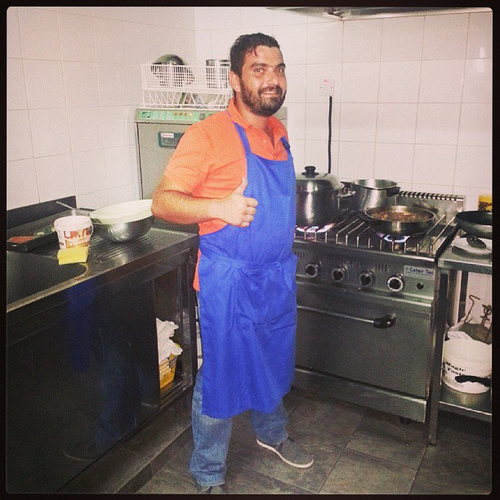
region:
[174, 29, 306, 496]
a man in a blue apron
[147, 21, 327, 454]
a man in an orange shirt and a blue apron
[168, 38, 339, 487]
a man wearing an orange shirt and a blue apron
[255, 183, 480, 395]
a stove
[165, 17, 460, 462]
a man cooking on the stove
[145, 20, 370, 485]
a man giving the thumbs up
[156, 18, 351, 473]
a man posing for a picture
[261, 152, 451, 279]
food cooking on the stove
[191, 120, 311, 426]
long blue apron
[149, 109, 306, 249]
orange shirt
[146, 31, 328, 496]
Man cooking in kitchen.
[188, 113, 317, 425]
Man wearing a blue apron.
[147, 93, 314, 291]
Man dressed in orange shirt.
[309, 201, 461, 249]
Frying pan filled with cooking food.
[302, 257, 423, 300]
Control knobs on front of stove.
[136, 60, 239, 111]
White rack filled with aluminum bowls.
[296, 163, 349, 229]
Covered pot on top of stove.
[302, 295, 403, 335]
Handle on front of oven door.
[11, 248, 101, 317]
Edge of kitchen sink.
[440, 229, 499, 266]
Spoon laying on small plate on counter.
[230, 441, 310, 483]
grey and black mens sneakers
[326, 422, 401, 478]
gray and dark gray stone floor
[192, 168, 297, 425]
bright blue mens apron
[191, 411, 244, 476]
light blue mens jeans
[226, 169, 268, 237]
hand showing the thumbs up sign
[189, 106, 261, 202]
orange colored polo t shirt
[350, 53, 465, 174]
white kitchen tile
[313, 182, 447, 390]
large stainless steel kitchen stove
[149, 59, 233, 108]
white dish rack above washer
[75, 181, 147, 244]
mixing and serving bowl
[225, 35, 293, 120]
a man's face sporting a beard.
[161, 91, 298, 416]
a blue apron tied in front.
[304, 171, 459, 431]
a large stainless steel range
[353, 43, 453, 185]
a white tile backsplash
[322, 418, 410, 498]
a grey ceramic tile floor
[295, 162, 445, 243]
pots and pans of food on the range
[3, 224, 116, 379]
a large stainless steel sink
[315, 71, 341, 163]
an electrical outlet with a flashing red timer.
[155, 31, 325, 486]
A man wearing an orange shirt, blue apron and blue jeans.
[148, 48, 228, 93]
cooking utensils in a wire basket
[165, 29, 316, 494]
man with a blue apron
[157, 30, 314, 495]
man with orange shirt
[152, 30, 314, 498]
man in school colors of Florida Gators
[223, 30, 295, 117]
face with facial hair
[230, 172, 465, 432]
a stainless steel stove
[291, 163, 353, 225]
a pot with a lid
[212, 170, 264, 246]
right handed thumbs up signal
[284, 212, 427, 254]
gas burners in the on position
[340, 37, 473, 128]
white tile wall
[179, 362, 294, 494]
a pair of denim pants